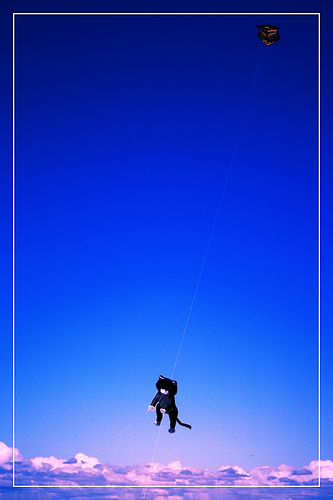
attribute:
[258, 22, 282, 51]
kite — yellow, black, badge shaped, green, floating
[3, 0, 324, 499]
sky — blue, clear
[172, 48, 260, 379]
string — white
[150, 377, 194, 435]
cat — flying, skydiving, stuffed, dressed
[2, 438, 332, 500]
clouds — purple, puffy, low, white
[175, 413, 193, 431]
tail — long, black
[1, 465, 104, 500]
cloud — dark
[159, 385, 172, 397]
snout — white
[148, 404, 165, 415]
paws — white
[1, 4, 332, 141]
top — weird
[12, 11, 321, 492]
border — white